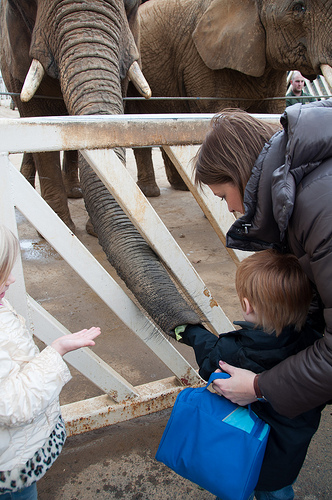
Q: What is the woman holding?
A: Blue bag.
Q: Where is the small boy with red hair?
A: Mother's arms.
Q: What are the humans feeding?
A: Elephants.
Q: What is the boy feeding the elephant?
A: Lettuce.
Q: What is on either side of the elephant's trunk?
A: Tusk.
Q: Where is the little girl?
A: Left.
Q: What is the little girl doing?
A: Holding out hand.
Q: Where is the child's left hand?
A: Inside the elephant's trunk.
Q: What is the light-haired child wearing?
A: A dark blue jacket.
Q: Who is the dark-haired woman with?
A: The little boy wearing the dark blue jacket.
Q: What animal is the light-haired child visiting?
A: An elephant.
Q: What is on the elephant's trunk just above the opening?
A: Hair.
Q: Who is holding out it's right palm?
A: The light-haired girl.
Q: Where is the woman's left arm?
A: Around the child standing next to her.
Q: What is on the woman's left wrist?
A: A watch.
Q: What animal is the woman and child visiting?
A: An elephant.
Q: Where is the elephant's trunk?
A: Between the white posts.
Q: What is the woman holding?
A: A blue bag.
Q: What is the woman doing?
A: Helping the boy.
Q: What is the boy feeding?
A: An elephant.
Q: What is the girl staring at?
A: Her hand.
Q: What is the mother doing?
A: Helping her son.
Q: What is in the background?
A: A second elephant.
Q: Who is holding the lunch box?
A: The woman.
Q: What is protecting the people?
A: A metal pole.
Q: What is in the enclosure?
A: Two large elephants.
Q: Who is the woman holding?
A: The boy.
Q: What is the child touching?
A: Snout.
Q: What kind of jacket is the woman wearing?
A: Puffy.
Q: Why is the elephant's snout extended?
A: Wants a handout.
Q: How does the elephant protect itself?
A: With tusks.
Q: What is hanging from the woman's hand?
A: Lunchbox.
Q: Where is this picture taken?
A: A zoo.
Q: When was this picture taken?
A: Daytime.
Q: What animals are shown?
A: Elephants.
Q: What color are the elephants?
A: Grey.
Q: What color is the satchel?
A: Blue.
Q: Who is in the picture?
A: A woman and two children.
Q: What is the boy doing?
A: Feeding the elephant.